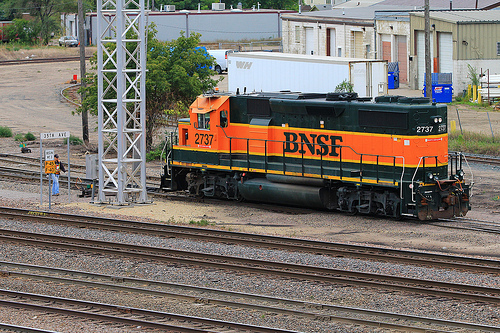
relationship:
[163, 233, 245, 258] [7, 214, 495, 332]
gravel lying between railroad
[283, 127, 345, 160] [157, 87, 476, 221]
black words on train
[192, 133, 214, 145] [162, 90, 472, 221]
number on car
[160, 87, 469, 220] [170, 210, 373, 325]
car on track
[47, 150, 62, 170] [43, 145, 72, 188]
head of a person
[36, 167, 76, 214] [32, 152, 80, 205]
legs of a person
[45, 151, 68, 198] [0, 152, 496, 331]
person walking on bunch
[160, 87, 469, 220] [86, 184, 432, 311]
car on rail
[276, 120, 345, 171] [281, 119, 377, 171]
characters on train body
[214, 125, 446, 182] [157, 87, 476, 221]
hand rails on train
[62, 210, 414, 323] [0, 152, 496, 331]
bunch of bunch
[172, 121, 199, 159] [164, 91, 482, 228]
door of a train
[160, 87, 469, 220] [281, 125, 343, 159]
car has logo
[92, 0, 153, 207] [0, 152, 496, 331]
tower beside bunch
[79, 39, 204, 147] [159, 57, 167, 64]
tree has leaves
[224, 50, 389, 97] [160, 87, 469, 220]
trailer behind car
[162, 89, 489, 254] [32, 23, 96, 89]
car in background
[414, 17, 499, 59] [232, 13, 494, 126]
building in background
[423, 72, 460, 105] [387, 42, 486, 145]
dumpster in background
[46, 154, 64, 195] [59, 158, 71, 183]
person has arm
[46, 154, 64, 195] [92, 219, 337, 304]
person walking railroad